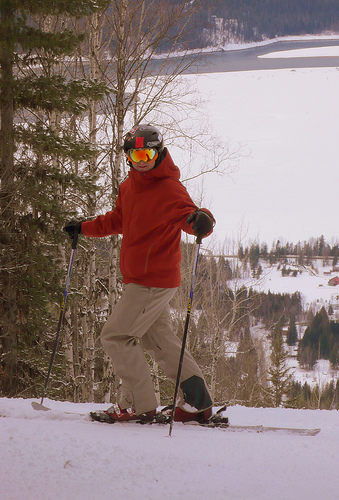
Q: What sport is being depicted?
A: Skiing.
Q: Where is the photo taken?
A: Mountains.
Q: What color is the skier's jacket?
A: Red.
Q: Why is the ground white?
A: Snow.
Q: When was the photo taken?
A: Winter.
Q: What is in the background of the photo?
A: River.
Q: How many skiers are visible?
A: One.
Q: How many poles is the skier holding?
A: Two.